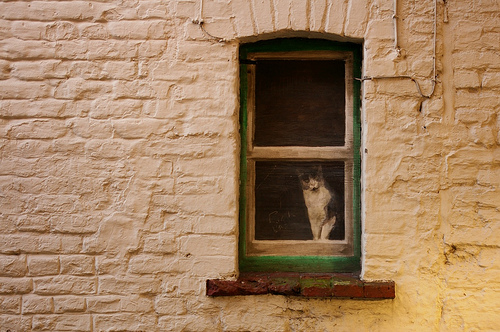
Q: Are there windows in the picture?
A: Yes, there is a window.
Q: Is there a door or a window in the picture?
A: Yes, there is a window.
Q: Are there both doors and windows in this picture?
A: No, there is a window but no doors.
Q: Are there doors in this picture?
A: No, there are no doors.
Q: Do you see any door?
A: No, there are no doors.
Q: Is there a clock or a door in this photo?
A: No, there are no doors or clocks.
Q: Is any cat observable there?
A: Yes, there is a cat.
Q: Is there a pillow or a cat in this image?
A: Yes, there is a cat.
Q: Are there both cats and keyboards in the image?
A: No, there is a cat but no keyboards.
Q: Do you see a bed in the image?
A: No, there are no beds.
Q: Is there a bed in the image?
A: No, there are no beds.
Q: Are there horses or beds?
A: No, there are no beds or horses.